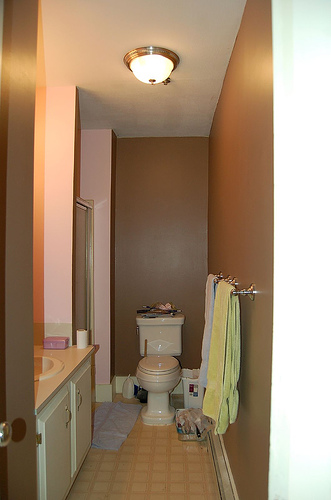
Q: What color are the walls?
A: Beige.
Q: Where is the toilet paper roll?
A: On the sink.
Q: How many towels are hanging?
A: 2.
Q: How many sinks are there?
A: One.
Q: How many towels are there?
A: Two.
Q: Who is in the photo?
A: No one.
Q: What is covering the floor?
A: Tile.